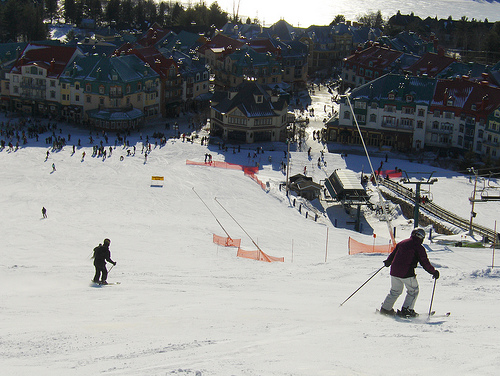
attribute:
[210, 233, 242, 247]
netting — orange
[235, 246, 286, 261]
netting — orange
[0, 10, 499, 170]
town — large, below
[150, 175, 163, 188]
flag — red, white, blue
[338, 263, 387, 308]
ski pole — black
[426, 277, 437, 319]
ski pole — black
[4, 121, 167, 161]
spectators — bottom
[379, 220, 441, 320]
skier — red, white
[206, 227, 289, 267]
fence — orange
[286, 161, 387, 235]
ski station — little, small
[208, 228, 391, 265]
fences — red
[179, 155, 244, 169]
fences — red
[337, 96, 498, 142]
cabin — white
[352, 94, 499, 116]
roof — green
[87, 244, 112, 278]
suit — black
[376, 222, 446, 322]
person — skiing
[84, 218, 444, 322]
people — skiing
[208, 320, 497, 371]
snow — white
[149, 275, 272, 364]
snow — white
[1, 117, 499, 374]
snow — white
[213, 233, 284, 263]
barrier — orange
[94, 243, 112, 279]
clothes — black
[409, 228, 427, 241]
helmet — black, white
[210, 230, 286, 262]
barriers — orange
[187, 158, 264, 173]
barrier — orange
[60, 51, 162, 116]
house — yellow